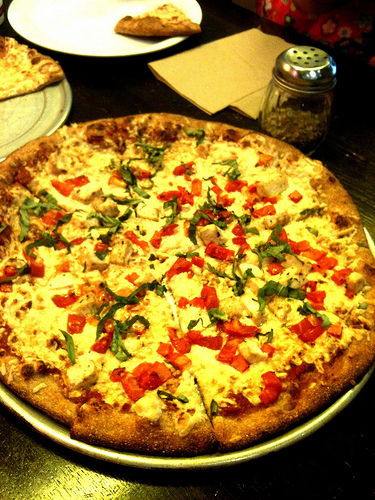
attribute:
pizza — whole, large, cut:
[1, 109, 373, 457]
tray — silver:
[1, 222, 372, 476]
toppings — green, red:
[7, 146, 357, 406]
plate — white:
[4, 2, 204, 58]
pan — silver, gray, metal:
[0, 79, 74, 165]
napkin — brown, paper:
[146, 27, 297, 120]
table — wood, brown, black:
[3, 1, 374, 496]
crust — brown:
[2, 111, 374, 457]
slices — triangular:
[2, 113, 372, 458]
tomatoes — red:
[0, 166, 355, 407]